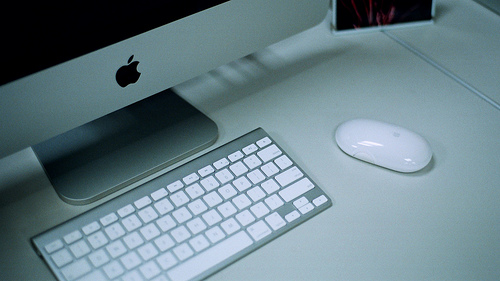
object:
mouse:
[334, 118, 433, 173]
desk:
[0, 1, 499, 280]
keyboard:
[31, 127, 332, 280]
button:
[256, 136, 272, 148]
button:
[274, 166, 305, 188]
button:
[214, 168, 235, 184]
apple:
[114, 54, 142, 88]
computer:
[0, 1, 331, 206]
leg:
[32, 87, 219, 207]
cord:
[381, 28, 500, 109]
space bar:
[166, 230, 254, 280]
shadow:
[2, 43, 351, 207]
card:
[333, 0, 438, 34]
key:
[186, 199, 208, 216]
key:
[216, 201, 238, 218]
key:
[122, 215, 141, 230]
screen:
[1, 0, 229, 89]